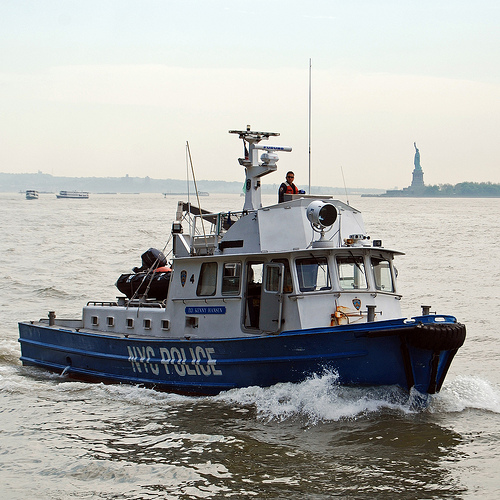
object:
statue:
[412, 141, 422, 171]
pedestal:
[412, 170, 426, 192]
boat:
[16, 126, 466, 402]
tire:
[412, 320, 466, 350]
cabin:
[164, 197, 405, 341]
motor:
[132, 247, 168, 273]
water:
[59, 364, 70, 378]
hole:
[64, 355, 72, 368]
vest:
[282, 180, 301, 198]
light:
[305, 199, 339, 229]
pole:
[320, 227, 327, 241]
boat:
[56, 190, 89, 199]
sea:
[2, 195, 498, 500]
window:
[223, 258, 243, 299]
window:
[295, 258, 335, 292]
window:
[338, 256, 369, 291]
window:
[371, 258, 396, 292]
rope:
[128, 233, 170, 306]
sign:
[126, 345, 224, 377]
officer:
[277, 171, 300, 204]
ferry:
[26, 190, 40, 199]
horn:
[351, 234, 372, 248]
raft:
[117, 274, 172, 300]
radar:
[254, 143, 294, 164]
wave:
[218, 359, 500, 425]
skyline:
[1, 174, 392, 196]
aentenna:
[307, 58, 314, 196]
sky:
[0, 2, 500, 190]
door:
[258, 260, 283, 335]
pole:
[186, 139, 208, 238]